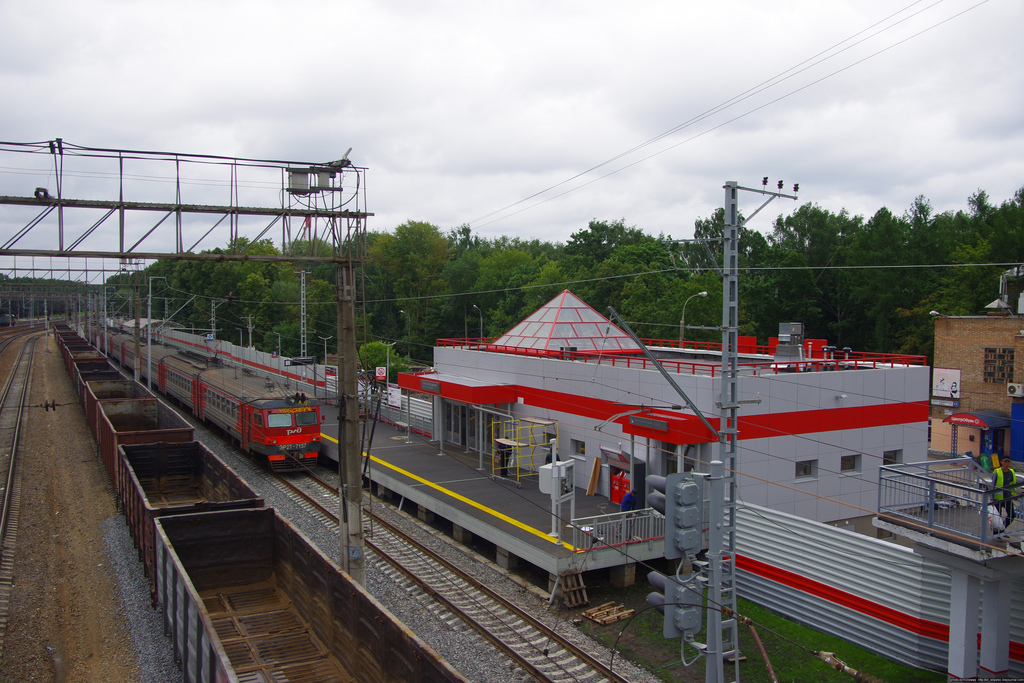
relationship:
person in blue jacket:
[609, 483, 648, 538] [610, 488, 645, 517]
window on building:
[565, 432, 592, 464] [921, 287, 1021, 475]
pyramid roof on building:
[482, 283, 651, 359] [391, 281, 936, 551]